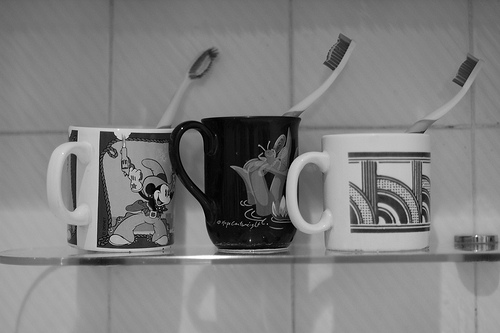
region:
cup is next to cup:
[43, 121, 176, 255]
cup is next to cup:
[167, 112, 298, 255]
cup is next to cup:
[285, 130, 433, 252]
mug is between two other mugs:
[167, 117, 303, 254]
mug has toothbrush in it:
[44, 122, 176, 252]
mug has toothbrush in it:
[169, 115, 302, 254]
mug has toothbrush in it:
[282, 130, 432, 252]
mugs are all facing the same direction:
[42, 112, 434, 254]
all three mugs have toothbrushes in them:
[44, 32, 482, 254]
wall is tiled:
[1, 0, 499, 332]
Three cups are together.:
[48, 116, 431, 256]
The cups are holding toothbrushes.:
[48, 34, 481, 251]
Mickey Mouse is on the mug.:
[103, 153, 170, 245]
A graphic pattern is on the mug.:
[351, 153, 426, 228]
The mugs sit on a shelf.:
[0, 254, 499, 267]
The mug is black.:
[212, 123, 250, 153]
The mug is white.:
[327, 157, 344, 215]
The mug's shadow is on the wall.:
[336, 265, 436, 332]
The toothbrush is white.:
[163, 98, 175, 123]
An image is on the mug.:
[231, 136, 287, 216]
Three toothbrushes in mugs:
[43, 29, 491, 259]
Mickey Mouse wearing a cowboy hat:
[109, 129, 174, 254]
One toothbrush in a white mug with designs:
[288, 51, 487, 252]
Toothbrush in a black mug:
[168, 29, 353, 251]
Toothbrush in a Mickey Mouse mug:
[45, 47, 217, 259]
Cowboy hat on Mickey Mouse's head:
[139, 155, 171, 190]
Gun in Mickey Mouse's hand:
[117, 129, 141, 189]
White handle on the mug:
[285, 147, 330, 234]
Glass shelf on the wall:
[0, 240, 495, 267]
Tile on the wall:
[0, 1, 497, 331]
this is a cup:
[11, 12, 178, 277]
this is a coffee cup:
[32, 52, 199, 289]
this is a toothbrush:
[137, 16, 237, 163]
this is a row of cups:
[55, 74, 450, 298]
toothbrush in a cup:
[3, 13, 230, 300]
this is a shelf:
[5, 225, 498, 307]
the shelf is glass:
[5, 225, 499, 314]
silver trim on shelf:
[15, 220, 499, 295]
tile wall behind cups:
[16, 18, 480, 330]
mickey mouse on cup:
[79, 136, 226, 258]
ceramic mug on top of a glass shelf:
[45, 123, 177, 254]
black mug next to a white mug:
[168, 115, 300, 250]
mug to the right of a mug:
[284, 133, 434, 251]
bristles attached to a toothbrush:
[453, 54, 478, 87]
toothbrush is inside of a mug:
[403, 53, 485, 130]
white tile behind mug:
[297, 127, 475, 253]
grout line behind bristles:
[465, 0, 480, 240]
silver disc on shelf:
[454, 233, 495, 246]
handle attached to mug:
[284, 148, 332, 228]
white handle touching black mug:
[286, 150, 334, 227]